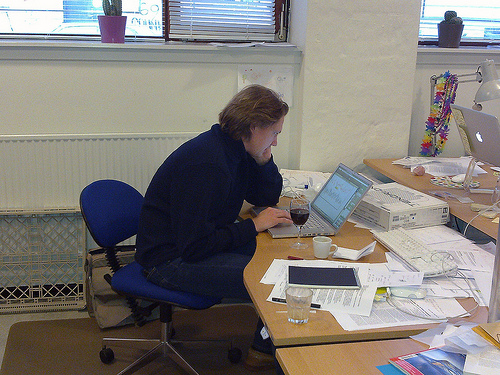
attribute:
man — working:
[119, 73, 282, 365]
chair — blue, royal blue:
[78, 172, 250, 373]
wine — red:
[287, 206, 310, 227]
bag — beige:
[77, 243, 162, 333]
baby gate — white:
[2, 208, 90, 314]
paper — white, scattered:
[420, 227, 491, 281]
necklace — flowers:
[426, 73, 456, 161]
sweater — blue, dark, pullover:
[137, 125, 282, 271]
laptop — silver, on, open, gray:
[247, 160, 373, 241]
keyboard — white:
[369, 226, 459, 281]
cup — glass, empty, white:
[310, 235, 338, 261]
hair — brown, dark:
[217, 82, 288, 139]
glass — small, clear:
[282, 285, 316, 329]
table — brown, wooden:
[355, 139, 498, 243]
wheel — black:
[92, 345, 116, 369]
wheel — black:
[223, 348, 246, 365]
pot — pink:
[97, 16, 130, 44]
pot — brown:
[433, 22, 464, 48]